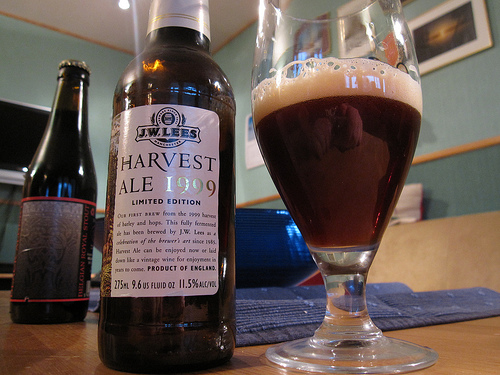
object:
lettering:
[117, 151, 217, 198]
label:
[100, 103, 220, 297]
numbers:
[112, 278, 218, 291]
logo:
[135, 107, 201, 149]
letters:
[72, 202, 91, 298]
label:
[10, 195, 98, 302]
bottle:
[97, 0, 236, 374]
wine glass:
[250, 0, 439, 375]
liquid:
[254, 94, 421, 248]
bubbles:
[249, 57, 423, 126]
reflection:
[275, 104, 391, 247]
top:
[57, 59, 92, 75]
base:
[263, 334, 438, 374]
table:
[1, 289, 499, 374]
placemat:
[88, 282, 499, 347]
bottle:
[10, 59, 98, 325]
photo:
[406, 0, 492, 77]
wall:
[420, 88, 500, 225]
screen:
[0, 100, 51, 173]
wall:
[0, 16, 138, 233]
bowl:
[93, 202, 323, 287]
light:
[117, 0, 130, 11]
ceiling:
[0, 0, 291, 56]